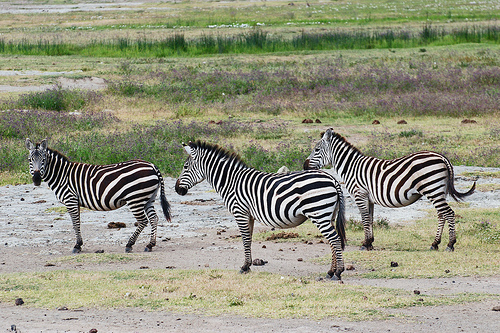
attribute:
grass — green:
[0, 30, 499, 66]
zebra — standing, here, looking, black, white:
[24, 137, 170, 253]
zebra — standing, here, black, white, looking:
[175, 140, 349, 280]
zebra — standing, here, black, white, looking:
[303, 127, 477, 251]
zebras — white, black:
[24, 128, 477, 281]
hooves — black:
[239, 263, 345, 282]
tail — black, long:
[159, 196, 172, 222]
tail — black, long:
[335, 213, 347, 251]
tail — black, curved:
[449, 181, 475, 202]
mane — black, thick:
[37, 145, 72, 162]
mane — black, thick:
[189, 141, 250, 168]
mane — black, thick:
[320, 130, 364, 159]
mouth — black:
[176, 185, 188, 197]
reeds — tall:
[1, 25, 499, 56]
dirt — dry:
[0, 164, 499, 332]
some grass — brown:
[3, 55, 499, 147]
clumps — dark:
[10, 191, 402, 284]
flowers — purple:
[3, 108, 122, 139]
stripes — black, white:
[64, 165, 144, 203]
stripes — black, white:
[241, 175, 310, 215]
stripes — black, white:
[358, 160, 416, 199]